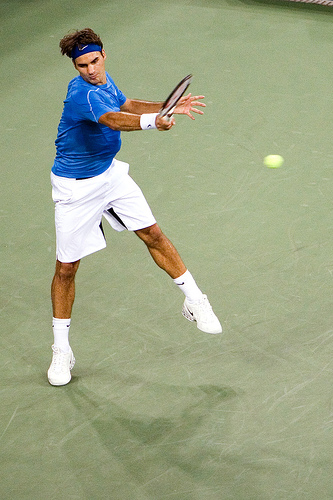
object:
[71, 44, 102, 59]
band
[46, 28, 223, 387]
man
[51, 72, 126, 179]
shirt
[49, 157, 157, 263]
shorts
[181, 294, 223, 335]
shoe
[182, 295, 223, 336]
foot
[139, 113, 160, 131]
wrist band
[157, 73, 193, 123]
racket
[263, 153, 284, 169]
ball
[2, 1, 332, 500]
air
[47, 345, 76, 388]
shoe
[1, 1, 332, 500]
surface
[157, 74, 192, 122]
tennis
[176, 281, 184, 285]
logo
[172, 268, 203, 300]
sock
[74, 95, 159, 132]
arm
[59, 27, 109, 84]
head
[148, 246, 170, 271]
muscle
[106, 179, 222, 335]
leg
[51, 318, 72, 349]
socks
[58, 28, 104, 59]
hair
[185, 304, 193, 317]
check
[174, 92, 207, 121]
hand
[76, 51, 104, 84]
face